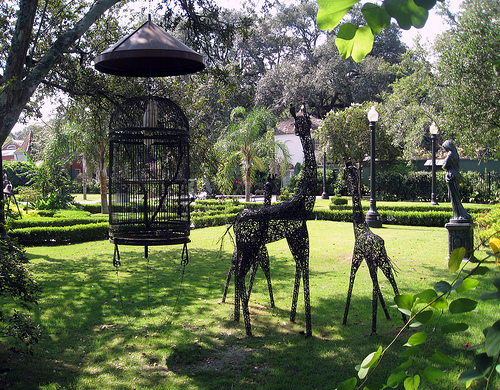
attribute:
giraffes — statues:
[226, 104, 416, 339]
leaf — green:
[329, 14, 383, 70]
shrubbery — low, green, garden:
[9, 236, 84, 300]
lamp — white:
[365, 97, 389, 141]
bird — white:
[138, 98, 161, 146]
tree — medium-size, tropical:
[188, 81, 315, 195]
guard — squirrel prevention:
[93, 18, 205, 83]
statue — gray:
[433, 137, 487, 258]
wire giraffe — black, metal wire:
[340, 143, 408, 335]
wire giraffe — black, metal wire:
[219, 91, 326, 339]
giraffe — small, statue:
[326, 158, 412, 350]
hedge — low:
[5, 176, 320, 261]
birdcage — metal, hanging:
[107, 97, 187, 244]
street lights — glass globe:
[429, 121, 439, 206]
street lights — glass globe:
[365, 104, 381, 226]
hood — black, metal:
[93, 23, 209, 73]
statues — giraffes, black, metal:
[195, 106, 408, 356]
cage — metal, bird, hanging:
[95, 92, 205, 275]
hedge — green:
[348, 163, 481, 198]